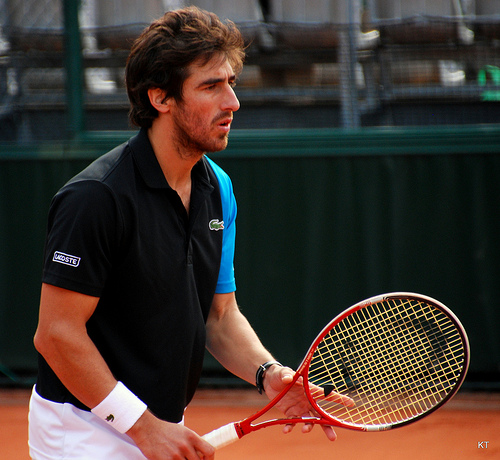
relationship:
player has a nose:
[28, 6, 356, 460] [219, 81, 239, 117]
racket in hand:
[147, 290, 470, 460] [136, 417, 217, 460]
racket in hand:
[147, 290, 470, 460] [258, 366, 357, 443]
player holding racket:
[28, 6, 356, 460] [147, 290, 470, 460]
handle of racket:
[180, 422, 240, 452] [147, 290, 470, 460]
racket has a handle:
[147, 290, 470, 460] [180, 422, 240, 452]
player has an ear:
[28, 6, 356, 460] [145, 83, 171, 114]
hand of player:
[136, 417, 217, 460] [28, 6, 356, 460]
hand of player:
[258, 366, 357, 443] [28, 6, 356, 460]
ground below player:
[0, 388, 498, 460] [28, 6, 356, 460]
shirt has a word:
[33, 125, 235, 424] [50, 251, 80, 267]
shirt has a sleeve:
[33, 125, 235, 424] [205, 156, 238, 295]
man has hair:
[28, 6, 356, 460] [124, 7, 250, 129]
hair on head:
[124, 7, 250, 129] [124, 7, 241, 153]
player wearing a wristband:
[28, 6, 356, 460] [91, 380, 148, 436]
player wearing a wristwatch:
[28, 6, 356, 460] [255, 360, 281, 397]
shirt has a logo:
[33, 125, 235, 424] [209, 219, 225, 232]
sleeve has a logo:
[41, 180, 117, 299] [50, 251, 80, 267]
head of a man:
[124, 7, 241, 153] [28, 6, 356, 460]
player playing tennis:
[28, 6, 356, 460] [191, 289, 471, 460]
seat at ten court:
[0, 87, 499, 137] [1, 385, 498, 460]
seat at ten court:
[0, 45, 499, 67] [1, 385, 498, 460]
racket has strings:
[147, 290, 470, 460] [308, 299, 463, 426]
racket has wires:
[147, 290, 470, 460] [308, 299, 463, 426]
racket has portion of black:
[147, 290, 470, 460] [389, 294, 468, 432]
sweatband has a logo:
[91, 380, 148, 436] [103, 414, 117, 423]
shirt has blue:
[33, 125, 235, 424] [203, 151, 236, 296]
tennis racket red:
[191, 289, 471, 460] [234, 291, 470, 439]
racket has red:
[147, 290, 470, 460] [234, 291, 470, 439]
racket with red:
[147, 290, 470, 460] [234, 291, 470, 439]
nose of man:
[219, 81, 239, 117] [28, 6, 356, 460]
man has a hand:
[28, 6, 356, 460] [136, 417, 217, 460]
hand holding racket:
[136, 417, 217, 460] [147, 290, 470, 460]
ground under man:
[0, 388, 498, 460] [28, 6, 356, 460]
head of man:
[124, 7, 241, 153] [28, 6, 356, 460]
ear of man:
[145, 83, 171, 114] [28, 6, 356, 460]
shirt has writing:
[33, 125, 235, 424] [50, 251, 80, 267]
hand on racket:
[258, 366, 357, 443] [147, 290, 470, 460]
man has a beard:
[28, 6, 356, 460] [168, 103, 232, 159]